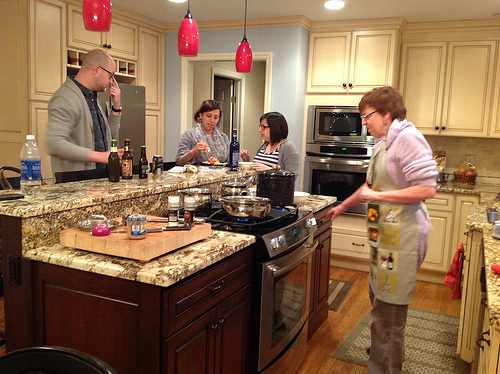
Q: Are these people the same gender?
A: No, they are both male and female.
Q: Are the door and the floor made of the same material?
A: Yes, both the door and the floor are made of wood.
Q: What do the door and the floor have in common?
A: The material, both the door and the floor are wooden.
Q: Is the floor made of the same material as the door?
A: Yes, both the floor and the door are made of wood.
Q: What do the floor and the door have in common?
A: The material, both the floor and the door are wooden.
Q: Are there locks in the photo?
A: No, there are no locks.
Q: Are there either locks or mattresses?
A: No, there are no locks or mattresses.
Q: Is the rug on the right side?
A: Yes, the rug is on the right of the image.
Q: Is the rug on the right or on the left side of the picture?
A: The rug is on the right of the image.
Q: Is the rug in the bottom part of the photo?
A: Yes, the rug is in the bottom of the image.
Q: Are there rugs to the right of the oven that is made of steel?
A: Yes, there is a rug to the right of the oven.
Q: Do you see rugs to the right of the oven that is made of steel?
A: Yes, there is a rug to the right of the oven.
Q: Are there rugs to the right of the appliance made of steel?
A: Yes, there is a rug to the right of the oven.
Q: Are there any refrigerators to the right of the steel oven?
A: No, there is a rug to the right of the oven.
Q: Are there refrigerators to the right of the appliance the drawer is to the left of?
A: No, there is a rug to the right of the oven.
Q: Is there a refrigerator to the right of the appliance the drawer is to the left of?
A: No, there is a rug to the right of the oven.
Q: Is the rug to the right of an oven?
A: Yes, the rug is to the right of an oven.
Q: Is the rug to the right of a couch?
A: No, the rug is to the right of an oven.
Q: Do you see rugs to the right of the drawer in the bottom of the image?
A: Yes, there is a rug to the right of the drawer.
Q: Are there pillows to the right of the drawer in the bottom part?
A: No, there is a rug to the right of the drawer.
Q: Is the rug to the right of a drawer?
A: Yes, the rug is to the right of a drawer.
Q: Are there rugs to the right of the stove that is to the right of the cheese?
A: Yes, there is a rug to the right of the stove.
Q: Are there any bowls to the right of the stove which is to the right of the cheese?
A: No, there is a rug to the right of the stove.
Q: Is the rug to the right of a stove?
A: Yes, the rug is to the right of a stove.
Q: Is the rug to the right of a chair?
A: No, the rug is to the right of a stove.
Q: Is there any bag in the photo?
A: No, there are no bags.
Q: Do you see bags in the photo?
A: No, there are no bags.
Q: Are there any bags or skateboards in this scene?
A: No, there are no bags or skateboards.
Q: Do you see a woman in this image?
A: Yes, there is a woman.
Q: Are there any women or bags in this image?
A: Yes, there is a woman.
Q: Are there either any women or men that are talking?
A: Yes, the woman is talking.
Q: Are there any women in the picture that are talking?
A: Yes, there is a woman that is talking.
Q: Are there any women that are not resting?
A: Yes, there is a woman that is talking.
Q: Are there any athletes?
A: No, there are no athletes.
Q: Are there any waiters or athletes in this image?
A: No, there are no athletes or waiters.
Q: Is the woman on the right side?
A: Yes, the woman is on the right of the image.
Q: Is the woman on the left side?
A: No, the woman is on the right of the image.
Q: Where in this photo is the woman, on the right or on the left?
A: The woman is on the right of the image.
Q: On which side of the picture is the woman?
A: The woman is on the right of the image.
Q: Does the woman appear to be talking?
A: Yes, the woman is talking.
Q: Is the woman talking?
A: Yes, the woman is talking.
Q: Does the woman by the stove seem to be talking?
A: Yes, the woman is talking.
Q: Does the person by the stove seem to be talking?
A: Yes, the woman is talking.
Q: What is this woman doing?
A: The woman is talking.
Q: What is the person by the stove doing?
A: The woman is talking.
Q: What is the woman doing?
A: The woman is talking.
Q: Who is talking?
A: The woman is talking.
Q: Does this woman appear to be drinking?
A: No, the woman is talking.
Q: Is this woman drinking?
A: No, the woman is talking.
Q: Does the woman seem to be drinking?
A: No, the woman is talking.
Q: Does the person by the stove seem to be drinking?
A: No, the woman is talking.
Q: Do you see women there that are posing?
A: No, there is a woman but she is talking.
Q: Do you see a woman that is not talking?
A: No, there is a woman but she is talking.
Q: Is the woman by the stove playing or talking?
A: The woman is talking.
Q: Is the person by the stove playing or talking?
A: The woman is talking.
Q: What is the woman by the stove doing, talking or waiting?
A: The woman is talking.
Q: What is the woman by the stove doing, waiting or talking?
A: The woman is talking.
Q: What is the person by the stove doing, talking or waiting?
A: The woman is talking.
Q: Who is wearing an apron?
A: The woman is wearing an apron.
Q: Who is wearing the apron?
A: The woman is wearing an apron.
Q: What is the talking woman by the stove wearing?
A: The woman is wearing an apron.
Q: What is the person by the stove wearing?
A: The woman is wearing an apron.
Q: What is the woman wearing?
A: The woman is wearing an apron.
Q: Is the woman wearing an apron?
A: Yes, the woman is wearing an apron.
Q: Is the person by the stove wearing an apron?
A: Yes, the woman is wearing an apron.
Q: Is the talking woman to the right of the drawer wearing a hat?
A: No, the woman is wearing an apron.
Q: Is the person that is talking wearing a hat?
A: No, the woman is wearing an apron.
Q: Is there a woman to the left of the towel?
A: Yes, there is a woman to the left of the towel.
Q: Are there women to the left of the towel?
A: Yes, there is a woman to the left of the towel.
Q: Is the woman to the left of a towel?
A: Yes, the woman is to the left of a towel.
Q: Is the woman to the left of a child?
A: No, the woman is to the left of a towel.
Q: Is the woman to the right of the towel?
A: No, the woman is to the left of the towel.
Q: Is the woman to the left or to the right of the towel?
A: The woman is to the left of the towel.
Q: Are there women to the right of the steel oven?
A: Yes, there is a woman to the right of the oven.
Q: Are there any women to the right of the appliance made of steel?
A: Yes, there is a woman to the right of the oven.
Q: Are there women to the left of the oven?
A: No, the woman is to the right of the oven.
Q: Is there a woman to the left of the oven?
A: No, the woman is to the right of the oven.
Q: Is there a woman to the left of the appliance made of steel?
A: No, the woman is to the right of the oven.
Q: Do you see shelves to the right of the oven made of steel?
A: No, there is a woman to the right of the oven.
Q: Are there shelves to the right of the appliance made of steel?
A: No, there is a woman to the right of the oven.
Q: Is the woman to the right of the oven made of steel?
A: Yes, the woman is to the right of the oven.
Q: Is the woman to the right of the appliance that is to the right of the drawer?
A: Yes, the woman is to the right of the oven.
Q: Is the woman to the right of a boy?
A: No, the woman is to the right of the oven.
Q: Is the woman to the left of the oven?
A: No, the woman is to the right of the oven.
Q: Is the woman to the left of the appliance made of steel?
A: No, the woman is to the right of the oven.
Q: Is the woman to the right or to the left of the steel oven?
A: The woman is to the right of the oven.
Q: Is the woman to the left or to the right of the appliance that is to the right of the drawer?
A: The woman is to the right of the oven.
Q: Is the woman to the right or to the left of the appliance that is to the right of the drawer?
A: The woman is to the right of the oven.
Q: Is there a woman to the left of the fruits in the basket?
A: Yes, there is a woman to the left of the fruits.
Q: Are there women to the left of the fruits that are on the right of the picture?
A: Yes, there is a woman to the left of the fruits.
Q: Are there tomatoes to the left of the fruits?
A: No, there is a woman to the left of the fruits.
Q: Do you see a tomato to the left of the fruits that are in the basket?
A: No, there is a woman to the left of the fruits.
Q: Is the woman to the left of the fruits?
A: Yes, the woman is to the left of the fruits.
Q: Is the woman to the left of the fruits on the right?
A: Yes, the woman is to the left of the fruits.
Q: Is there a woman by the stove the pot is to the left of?
A: Yes, there is a woman by the stove.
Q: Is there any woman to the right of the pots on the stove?
A: Yes, there is a woman to the right of the pots.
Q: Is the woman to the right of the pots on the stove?
A: Yes, the woman is to the right of the pots.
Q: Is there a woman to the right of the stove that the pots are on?
A: Yes, there is a woman to the right of the stove.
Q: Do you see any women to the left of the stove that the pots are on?
A: No, the woman is to the right of the stove.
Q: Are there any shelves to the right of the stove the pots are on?
A: No, there is a woman to the right of the stove.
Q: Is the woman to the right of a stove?
A: Yes, the woman is to the right of a stove.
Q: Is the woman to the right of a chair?
A: No, the woman is to the right of a stove.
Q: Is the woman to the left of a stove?
A: No, the woman is to the right of a stove.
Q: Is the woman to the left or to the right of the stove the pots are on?
A: The woman is to the right of the stove.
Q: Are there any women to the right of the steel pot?
A: Yes, there is a woman to the right of the pot.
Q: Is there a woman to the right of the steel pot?
A: Yes, there is a woman to the right of the pot.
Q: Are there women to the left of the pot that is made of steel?
A: No, the woman is to the right of the pot.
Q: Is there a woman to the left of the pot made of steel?
A: No, the woman is to the right of the pot.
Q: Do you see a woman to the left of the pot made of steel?
A: No, the woman is to the right of the pot.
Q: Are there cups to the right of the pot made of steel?
A: No, there is a woman to the right of the pot.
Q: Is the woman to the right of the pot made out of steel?
A: Yes, the woman is to the right of the pot.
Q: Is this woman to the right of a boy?
A: No, the woman is to the right of the pot.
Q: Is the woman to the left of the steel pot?
A: No, the woman is to the right of the pot.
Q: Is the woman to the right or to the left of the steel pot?
A: The woman is to the right of the pot.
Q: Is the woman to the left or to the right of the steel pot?
A: The woman is to the right of the pot.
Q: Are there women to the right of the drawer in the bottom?
A: Yes, there is a woman to the right of the drawer.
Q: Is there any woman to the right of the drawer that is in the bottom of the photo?
A: Yes, there is a woman to the right of the drawer.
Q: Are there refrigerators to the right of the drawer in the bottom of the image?
A: No, there is a woman to the right of the drawer.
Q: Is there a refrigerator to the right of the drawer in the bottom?
A: No, there is a woman to the right of the drawer.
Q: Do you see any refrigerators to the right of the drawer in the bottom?
A: No, there is a woman to the right of the drawer.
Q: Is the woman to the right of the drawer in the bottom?
A: Yes, the woman is to the right of the drawer.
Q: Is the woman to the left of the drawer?
A: No, the woman is to the right of the drawer.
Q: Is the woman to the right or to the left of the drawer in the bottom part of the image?
A: The woman is to the right of the drawer.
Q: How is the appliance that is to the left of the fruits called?
A: The appliance is a stove.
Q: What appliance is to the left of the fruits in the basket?
A: The appliance is a stove.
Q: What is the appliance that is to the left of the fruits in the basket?
A: The appliance is a stove.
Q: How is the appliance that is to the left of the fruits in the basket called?
A: The appliance is a stove.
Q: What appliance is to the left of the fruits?
A: The appliance is a stove.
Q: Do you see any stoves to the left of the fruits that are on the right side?
A: Yes, there is a stove to the left of the fruits.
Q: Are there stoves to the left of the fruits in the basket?
A: Yes, there is a stove to the left of the fruits.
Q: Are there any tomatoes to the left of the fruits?
A: No, there is a stove to the left of the fruits.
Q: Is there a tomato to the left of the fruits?
A: No, there is a stove to the left of the fruits.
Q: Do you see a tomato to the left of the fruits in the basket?
A: No, there is a stove to the left of the fruits.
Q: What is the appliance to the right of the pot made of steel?
A: The appliance is a stove.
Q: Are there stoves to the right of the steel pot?
A: Yes, there is a stove to the right of the pot.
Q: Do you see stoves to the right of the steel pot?
A: Yes, there is a stove to the right of the pot.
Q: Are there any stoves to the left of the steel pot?
A: No, the stove is to the right of the pot.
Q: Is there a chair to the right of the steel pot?
A: No, there is a stove to the right of the pot.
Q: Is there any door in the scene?
A: Yes, there is a door.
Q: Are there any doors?
A: Yes, there is a door.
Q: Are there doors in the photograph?
A: Yes, there is a door.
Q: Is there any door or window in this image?
A: Yes, there is a door.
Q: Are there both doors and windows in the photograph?
A: No, there is a door but no windows.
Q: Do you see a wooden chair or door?
A: Yes, there is a wood door.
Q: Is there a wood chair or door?
A: Yes, there is a wood door.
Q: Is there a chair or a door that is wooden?
A: Yes, the door is wooden.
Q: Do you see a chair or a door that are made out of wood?
A: Yes, the door is made of wood.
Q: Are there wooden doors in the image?
A: Yes, there is a wood door.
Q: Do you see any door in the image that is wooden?
A: Yes, there is a door that is wooden.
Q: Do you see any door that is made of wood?
A: Yes, there is a door that is made of wood.